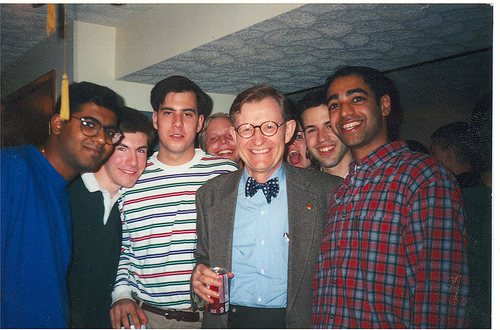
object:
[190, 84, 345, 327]
old man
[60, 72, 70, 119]
tassel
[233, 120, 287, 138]
glasses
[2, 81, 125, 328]
man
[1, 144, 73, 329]
blue shirt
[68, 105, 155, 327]
man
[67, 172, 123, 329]
black shirt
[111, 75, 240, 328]
man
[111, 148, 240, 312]
striped shirt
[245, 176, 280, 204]
bow tie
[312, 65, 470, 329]
man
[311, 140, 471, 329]
plaid shirt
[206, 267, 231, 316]
soda can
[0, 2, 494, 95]
ceiling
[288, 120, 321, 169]
person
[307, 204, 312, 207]
red pin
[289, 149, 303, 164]
open mouth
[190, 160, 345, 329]
blazer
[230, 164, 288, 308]
light blue shirt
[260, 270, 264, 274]
button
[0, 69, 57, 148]
door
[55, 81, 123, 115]
black hair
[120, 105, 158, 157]
brown hair